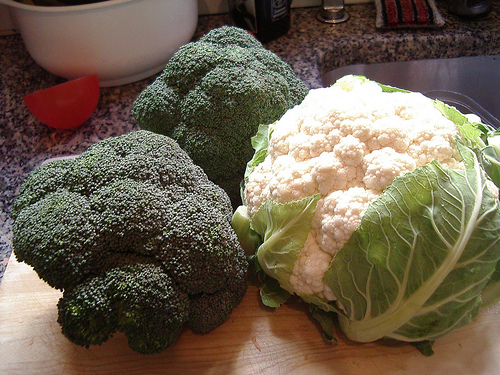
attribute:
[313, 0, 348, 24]
dispensor — soap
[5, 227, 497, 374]
cutting board — wooden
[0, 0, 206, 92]
bowl — large, white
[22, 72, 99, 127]
wedge — red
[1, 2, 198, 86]
bowl — round, white, plastic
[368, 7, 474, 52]
scrubber — plastic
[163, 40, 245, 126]
broccoli — green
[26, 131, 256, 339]
broccoli — firm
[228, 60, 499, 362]
cauliflower — open, wrapped, whole head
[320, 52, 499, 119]
sink — metal, deep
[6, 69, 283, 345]
broccoli — green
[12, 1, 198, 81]
bowl — white